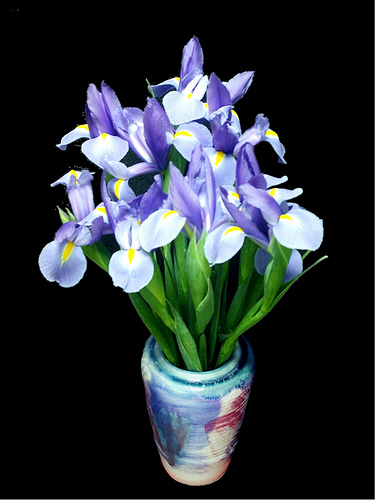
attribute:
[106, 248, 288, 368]
stems — green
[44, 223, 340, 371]
flowerstems — bright green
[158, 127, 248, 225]
flowers — purple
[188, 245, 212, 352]
stem — green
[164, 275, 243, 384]
stem — green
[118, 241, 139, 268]
flower — yellow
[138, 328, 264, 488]
vase — colorful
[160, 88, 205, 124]
heart petal — flower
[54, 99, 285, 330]
flowers — beautiful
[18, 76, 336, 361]
flowers — purple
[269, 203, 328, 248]
iris — purple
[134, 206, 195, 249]
iris — purple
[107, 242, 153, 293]
iris — purple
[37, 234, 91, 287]
iris — purple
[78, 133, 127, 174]
iris — purple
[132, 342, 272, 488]
vase — multicolored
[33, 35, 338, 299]
flowers — purple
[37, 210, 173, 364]
flower — lilac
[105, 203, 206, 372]
flower — lilac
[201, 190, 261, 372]
flower — lilac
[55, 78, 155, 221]
flower — lilac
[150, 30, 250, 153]
flower — lilac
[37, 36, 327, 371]
flowers — purple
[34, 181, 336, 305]
petals — white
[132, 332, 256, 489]
pot — flower, colorful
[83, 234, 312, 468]
stem — green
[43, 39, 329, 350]
flower — pink, purple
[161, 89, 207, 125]
petal — heart-shaped, flower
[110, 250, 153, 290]
petal — white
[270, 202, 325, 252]
petal — white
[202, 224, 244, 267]
petal — white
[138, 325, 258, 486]
pot — flower, blue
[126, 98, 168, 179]
flower — purple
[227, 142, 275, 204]
flower — purple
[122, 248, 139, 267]
center — yellow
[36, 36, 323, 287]
flowers — purple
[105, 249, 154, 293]
flower — white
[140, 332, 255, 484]
vase — ceramic